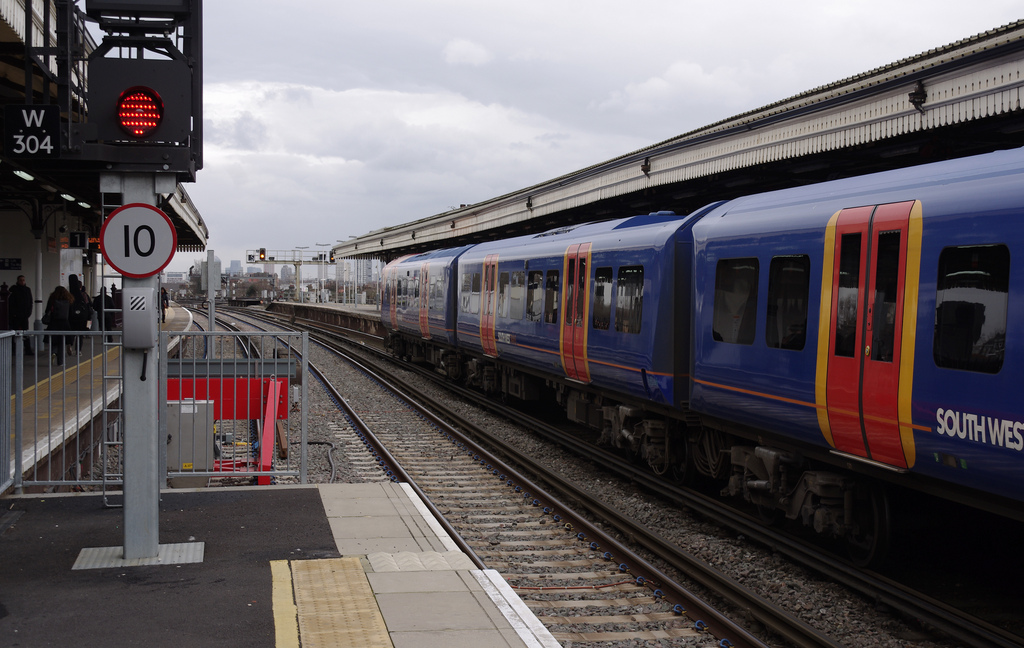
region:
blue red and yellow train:
[259, 159, 1022, 491]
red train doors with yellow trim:
[468, 194, 924, 473]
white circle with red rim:
[101, 203, 178, 274]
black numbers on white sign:
[117, 216, 163, 270]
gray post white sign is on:
[117, 168, 178, 561]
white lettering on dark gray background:
[15, 101, 54, 163]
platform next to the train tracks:
[6, 267, 501, 641]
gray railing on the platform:
[13, 308, 312, 487]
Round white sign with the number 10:
[92, 193, 184, 282]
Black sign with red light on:
[86, 51, 192, 176]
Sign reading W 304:
[1, 92, 63, 169]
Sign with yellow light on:
[251, 238, 271, 264]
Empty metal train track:
[210, 295, 843, 644]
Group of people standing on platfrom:
[5, 214, 190, 481]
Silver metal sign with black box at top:
[62, 4, 215, 573]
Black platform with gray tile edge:
[5, 480, 553, 645]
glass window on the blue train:
[934, 245, 1011, 370]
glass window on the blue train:
[829, 228, 848, 356]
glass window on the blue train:
[708, 256, 753, 337]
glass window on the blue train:
[605, 257, 634, 331]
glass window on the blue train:
[585, 258, 604, 325]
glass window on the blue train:
[571, 251, 575, 321]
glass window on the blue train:
[520, 258, 539, 326]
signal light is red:
[67, 43, 200, 179]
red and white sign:
[77, 198, 198, 282]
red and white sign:
[89, 192, 192, 297]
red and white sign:
[74, 195, 208, 291]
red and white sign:
[77, 189, 198, 292]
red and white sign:
[78, 195, 187, 303]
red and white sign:
[74, 192, 188, 300]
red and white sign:
[76, 195, 187, 288]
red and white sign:
[80, 195, 186, 288]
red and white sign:
[80, 195, 191, 294]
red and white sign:
[84, 193, 189, 293]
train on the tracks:
[363, 145, 1019, 510]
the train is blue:
[328, 133, 1014, 484]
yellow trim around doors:
[802, 189, 959, 475]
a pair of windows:
[686, 236, 835, 376]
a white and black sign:
[80, 180, 202, 298]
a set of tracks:
[238, 263, 843, 636]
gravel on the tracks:
[515, 468, 890, 637]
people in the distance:
[12, 241, 107, 374]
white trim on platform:
[380, 451, 548, 639]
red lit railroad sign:
[80, 47, 221, 184]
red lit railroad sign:
[62, 50, 208, 175]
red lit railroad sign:
[54, 44, 210, 169]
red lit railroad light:
[58, 50, 220, 184]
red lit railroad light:
[54, 29, 222, 186]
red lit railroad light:
[74, 48, 218, 192]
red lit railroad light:
[67, 40, 211, 190]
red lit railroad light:
[68, 45, 217, 189]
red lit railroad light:
[57, 44, 217, 190]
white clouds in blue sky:
[274, 135, 339, 194]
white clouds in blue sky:
[339, 77, 410, 138]